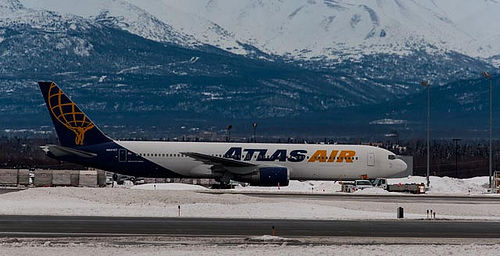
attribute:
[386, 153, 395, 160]
window — dark, tinted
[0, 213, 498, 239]
runway — black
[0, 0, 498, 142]
mountain — full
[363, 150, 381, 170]
door — side, Atlas Air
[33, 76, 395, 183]
plane — large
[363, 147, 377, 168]
door — white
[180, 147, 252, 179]
airplane — Atlas Air, large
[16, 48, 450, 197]
plane — white, black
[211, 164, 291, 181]
engine — jet, Atlas Air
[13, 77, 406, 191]
airplane — large, Atlas Air, white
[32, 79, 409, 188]
air liner — Atlas Air, passenger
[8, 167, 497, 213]
snow — white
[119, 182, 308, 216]
snow — dirty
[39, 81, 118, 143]
tail — dark blue